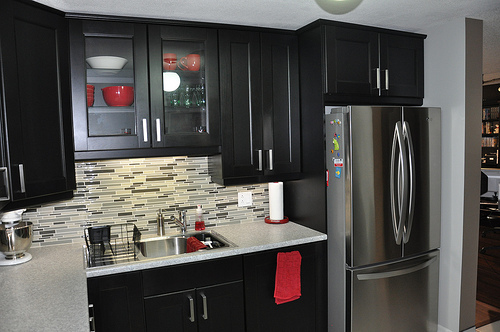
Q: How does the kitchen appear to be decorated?
A: Modern.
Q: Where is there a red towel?
A: On drawer handle.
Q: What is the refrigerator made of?
A: Stainless steel.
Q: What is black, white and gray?
A: The backsplash.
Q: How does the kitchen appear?
A: Neat and tidy.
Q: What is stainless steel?
A: The fridge.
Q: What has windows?
A: Two cabinets.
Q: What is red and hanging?
A: Dish towel.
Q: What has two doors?
A: Refrigerator.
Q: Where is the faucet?
A: Over the sink.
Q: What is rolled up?
A: Paper towels.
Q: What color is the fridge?
A: Silver.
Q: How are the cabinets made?
A: Of wood.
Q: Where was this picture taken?
A: In a kitchen.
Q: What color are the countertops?
A: White.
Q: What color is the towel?
A: Red.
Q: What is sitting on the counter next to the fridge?
A: A paper towel rack.